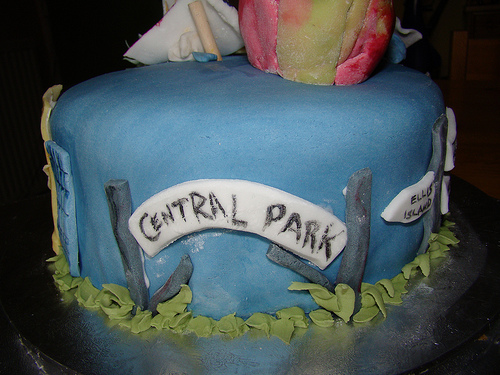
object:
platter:
[21, 271, 78, 363]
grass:
[104, 302, 257, 338]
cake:
[52, 71, 460, 329]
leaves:
[43, 220, 478, 334]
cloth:
[117, 0, 240, 69]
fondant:
[133, 1, 409, 88]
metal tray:
[6, 191, 499, 372]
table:
[6, 73, 499, 374]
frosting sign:
[131, 178, 348, 263]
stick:
[97, 178, 194, 299]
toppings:
[365, 7, 407, 81]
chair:
[445, 27, 498, 115]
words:
[133, 174, 459, 253]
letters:
[405, 183, 443, 218]